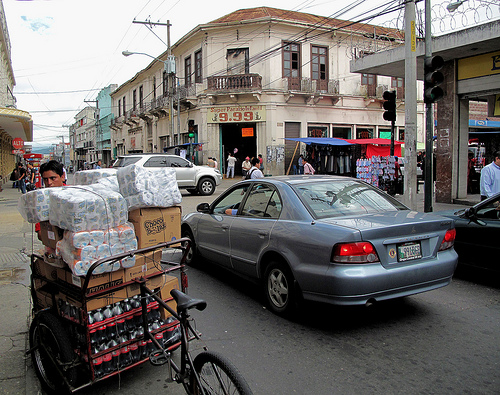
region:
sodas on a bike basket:
[50, 298, 182, 383]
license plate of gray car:
[390, 241, 433, 268]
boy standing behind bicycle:
[35, 159, 65, 189]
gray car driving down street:
[180, 163, 460, 330]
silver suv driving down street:
[112, 151, 222, 201]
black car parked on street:
[450, 183, 499, 283]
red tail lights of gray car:
[320, 222, 457, 266]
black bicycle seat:
[168, 279, 213, 319]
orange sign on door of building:
[235, 124, 256, 137]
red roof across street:
[351, 132, 411, 157]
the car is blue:
[195, 171, 474, 336]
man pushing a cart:
[23, 150, 246, 390]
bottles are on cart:
[80, 287, 220, 372]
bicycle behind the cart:
[125, 272, 250, 393]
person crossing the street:
[235, 149, 275, 196]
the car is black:
[441, 189, 498, 273]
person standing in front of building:
[221, 145, 241, 180]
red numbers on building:
[210, 103, 262, 127]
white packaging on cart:
[25, 163, 173, 273]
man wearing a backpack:
[240, 164, 262, 183]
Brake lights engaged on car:
[327, 220, 464, 268]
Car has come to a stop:
[180, 173, 462, 319]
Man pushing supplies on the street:
[18, 161, 169, 393]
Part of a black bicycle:
[147, 284, 258, 394]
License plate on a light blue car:
[381, 232, 439, 267]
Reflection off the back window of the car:
[288, 176, 411, 219]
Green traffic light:
[183, 115, 200, 165]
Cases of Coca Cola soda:
[85, 297, 172, 375]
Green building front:
[81, 62, 136, 154]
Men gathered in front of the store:
[212, 97, 317, 175]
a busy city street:
[23, 26, 485, 368]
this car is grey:
[206, 129, 434, 356]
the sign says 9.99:
[193, 96, 285, 150]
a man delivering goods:
[26, 147, 194, 377]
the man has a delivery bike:
[31, 159, 233, 384]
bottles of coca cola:
[71, 286, 170, 356]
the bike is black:
[34, 153, 254, 365]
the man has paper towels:
[69, 196, 156, 280]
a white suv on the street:
[99, 111, 211, 227]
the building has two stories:
[143, 21, 353, 218]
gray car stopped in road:
[200, 195, 455, 325]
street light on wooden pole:
[100, 45, 185, 80]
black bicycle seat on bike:
[160, 275, 210, 325]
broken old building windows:
[275, 45, 337, 90]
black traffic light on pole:
[420, 40, 442, 125]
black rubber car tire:
[190, 171, 222, 191]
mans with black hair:
[25, 151, 85, 192]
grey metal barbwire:
[417, 0, 497, 31]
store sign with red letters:
[191, 105, 258, 135]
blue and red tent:
[289, 127, 411, 160]